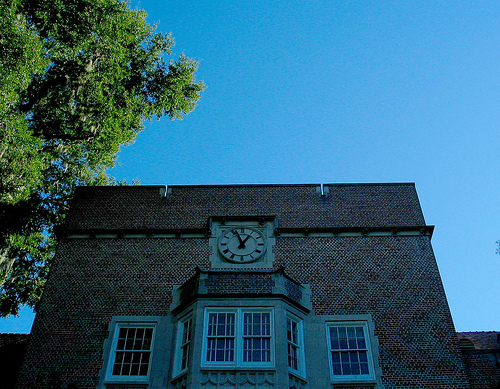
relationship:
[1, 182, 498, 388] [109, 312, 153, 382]
building has window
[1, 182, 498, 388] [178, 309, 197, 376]
building has windows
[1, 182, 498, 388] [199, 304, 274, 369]
building has window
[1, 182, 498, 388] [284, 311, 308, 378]
building has windows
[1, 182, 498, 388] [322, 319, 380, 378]
building has window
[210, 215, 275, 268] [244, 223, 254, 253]
clock on hand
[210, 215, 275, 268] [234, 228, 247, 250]
clock on hands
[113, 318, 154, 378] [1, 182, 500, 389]
window of building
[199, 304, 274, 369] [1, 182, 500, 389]
window of building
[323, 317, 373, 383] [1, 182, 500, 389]
window of building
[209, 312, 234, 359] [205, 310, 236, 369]
rods in window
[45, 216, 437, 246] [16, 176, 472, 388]
wood guttering on building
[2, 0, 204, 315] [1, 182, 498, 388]
tree top on building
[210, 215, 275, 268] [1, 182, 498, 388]
clock on building